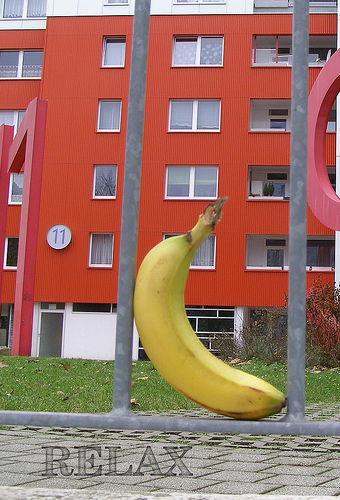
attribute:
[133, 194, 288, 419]
banana — ripe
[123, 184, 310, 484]
banana — big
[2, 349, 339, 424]
grass lawn — green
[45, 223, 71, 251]
circle — 11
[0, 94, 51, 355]
sculpture — large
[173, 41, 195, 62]
curtain — white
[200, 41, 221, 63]
curtain — white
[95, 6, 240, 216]
building — bright orange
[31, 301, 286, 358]
building — white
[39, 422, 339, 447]
grass — growing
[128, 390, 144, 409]
leaf — brown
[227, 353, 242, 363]
leaf — brown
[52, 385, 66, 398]
leaf — brown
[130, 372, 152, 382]
leaf — brown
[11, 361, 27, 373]
leaf — brown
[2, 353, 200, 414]
grass — green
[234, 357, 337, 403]
grass — green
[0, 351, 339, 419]
leaves — dry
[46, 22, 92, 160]
building — reddish orange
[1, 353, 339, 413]
grass — green